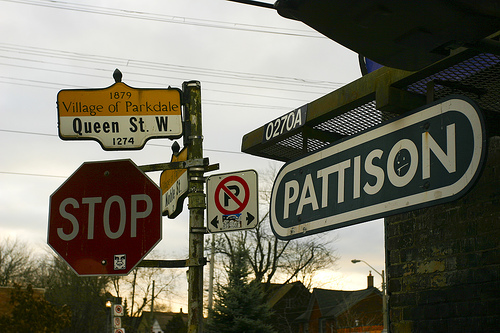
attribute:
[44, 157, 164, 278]
board — red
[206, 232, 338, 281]
trees — bare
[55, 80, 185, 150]
street sign — yellow and white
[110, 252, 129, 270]
sticker — square 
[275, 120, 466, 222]
letters — white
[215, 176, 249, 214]
circle — red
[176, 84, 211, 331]
pole — rusted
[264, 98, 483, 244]
sign — green , white , green and white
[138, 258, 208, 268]
brace — metal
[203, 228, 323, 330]
tree — evergreen  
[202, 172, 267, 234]
sign — white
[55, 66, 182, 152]
sign — irregular shaped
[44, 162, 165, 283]
stop sign — red and white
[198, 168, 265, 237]
sign — traffic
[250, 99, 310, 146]
number — black and white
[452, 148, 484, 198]
corners — rounded